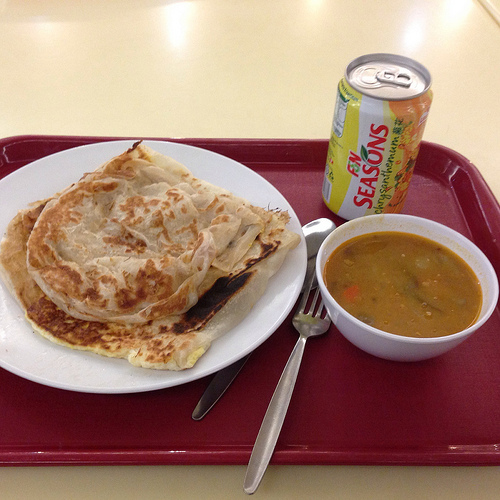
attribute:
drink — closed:
[317, 50, 434, 221]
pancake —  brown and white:
[25, 140, 256, 310]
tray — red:
[0, 130, 498, 471]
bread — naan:
[9, 134, 303, 376]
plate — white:
[0, 139, 309, 396]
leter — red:
[332, 117, 414, 233]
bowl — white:
[305, 205, 490, 372]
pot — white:
[309, 207, 499, 368]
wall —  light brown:
[4, 3, 498, 138]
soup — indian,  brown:
[322, 231, 479, 338]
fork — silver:
[240, 265, 333, 497]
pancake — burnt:
[2, 130, 300, 382]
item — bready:
[1, 133, 302, 374]